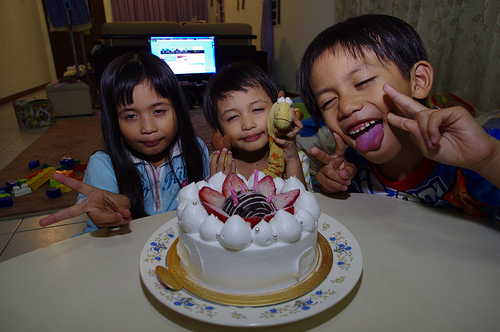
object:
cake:
[174, 170, 322, 296]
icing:
[175, 170, 321, 245]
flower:
[195, 171, 299, 228]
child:
[196, 61, 314, 194]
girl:
[39, 52, 211, 230]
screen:
[147, 36, 216, 74]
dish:
[135, 213, 365, 329]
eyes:
[352, 72, 380, 91]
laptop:
[143, 32, 225, 88]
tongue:
[353, 121, 383, 153]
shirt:
[74, 135, 214, 236]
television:
[144, 33, 223, 80]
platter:
[154, 226, 333, 308]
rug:
[0, 118, 104, 216]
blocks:
[0, 154, 84, 211]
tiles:
[2, 221, 91, 263]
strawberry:
[252, 176, 275, 196]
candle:
[227, 180, 239, 207]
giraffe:
[260, 90, 295, 179]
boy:
[293, 14, 499, 228]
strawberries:
[220, 171, 249, 197]